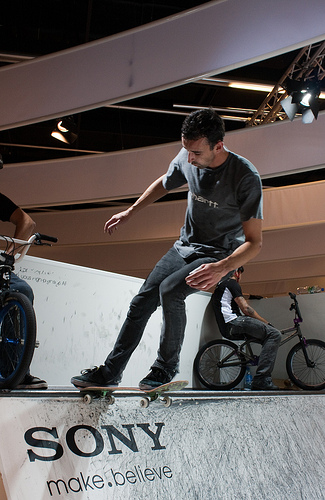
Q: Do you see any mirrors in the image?
A: No, there are no mirrors.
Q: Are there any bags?
A: No, there are no bags.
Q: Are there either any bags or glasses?
A: No, there are no bags or glasses.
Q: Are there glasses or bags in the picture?
A: No, there are no bags or glasses.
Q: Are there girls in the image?
A: No, there are no girls.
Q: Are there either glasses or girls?
A: No, there are no girls or glasses.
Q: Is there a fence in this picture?
A: No, there are no fences.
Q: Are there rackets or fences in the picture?
A: No, there are no fences or rackets.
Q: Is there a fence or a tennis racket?
A: No, there are no fences or rackets.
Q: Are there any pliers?
A: No, there are no pliers.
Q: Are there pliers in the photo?
A: No, there are no pliers.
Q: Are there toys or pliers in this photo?
A: No, there are no pliers or toys.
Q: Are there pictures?
A: No, there are no pictures.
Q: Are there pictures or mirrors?
A: No, there are no pictures or mirrors.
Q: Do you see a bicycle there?
A: Yes, there is a bicycle.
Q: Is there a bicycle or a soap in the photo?
A: Yes, there is a bicycle.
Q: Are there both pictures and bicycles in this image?
A: No, there is a bicycle but no pictures.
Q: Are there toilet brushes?
A: No, there are no toilet brushes.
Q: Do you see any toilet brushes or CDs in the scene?
A: No, there are no toilet brushes or cds.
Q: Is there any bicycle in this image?
A: Yes, there is a bicycle.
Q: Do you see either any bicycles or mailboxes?
A: Yes, there is a bicycle.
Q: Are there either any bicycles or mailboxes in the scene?
A: Yes, there is a bicycle.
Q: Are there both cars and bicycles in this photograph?
A: No, there is a bicycle but no cars.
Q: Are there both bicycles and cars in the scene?
A: No, there is a bicycle but no cars.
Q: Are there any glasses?
A: No, there are no glasses.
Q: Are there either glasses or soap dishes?
A: No, there are no glasses or soap dishes.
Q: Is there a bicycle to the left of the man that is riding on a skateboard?
A: Yes, there is a bicycle to the left of the man.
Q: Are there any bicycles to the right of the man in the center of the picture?
A: No, the bicycle is to the left of the man.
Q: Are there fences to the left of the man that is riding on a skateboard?
A: No, there is a bicycle to the left of the man.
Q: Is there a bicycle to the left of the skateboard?
A: Yes, there is a bicycle to the left of the skateboard.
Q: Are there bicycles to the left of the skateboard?
A: Yes, there is a bicycle to the left of the skateboard.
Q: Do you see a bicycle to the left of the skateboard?
A: Yes, there is a bicycle to the left of the skateboard.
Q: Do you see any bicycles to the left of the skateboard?
A: Yes, there is a bicycle to the left of the skateboard.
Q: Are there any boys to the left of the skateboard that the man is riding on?
A: No, there is a bicycle to the left of the skateboard.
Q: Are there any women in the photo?
A: No, there are no women.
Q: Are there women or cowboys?
A: No, there are no women or cowboys.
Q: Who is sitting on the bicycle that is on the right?
A: The man is sitting on the bicycle.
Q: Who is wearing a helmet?
A: The man is wearing a helmet.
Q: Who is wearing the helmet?
A: The man is wearing a helmet.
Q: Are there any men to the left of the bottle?
A: Yes, there is a man to the left of the bottle.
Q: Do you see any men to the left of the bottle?
A: Yes, there is a man to the left of the bottle.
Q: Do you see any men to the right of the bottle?
A: No, the man is to the left of the bottle.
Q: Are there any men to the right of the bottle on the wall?
A: No, the man is to the left of the bottle.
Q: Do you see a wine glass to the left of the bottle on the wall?
A: No, there is a man to the left of the bottle.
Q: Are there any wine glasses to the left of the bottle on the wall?
A: No, there is a man to the left of the bottle.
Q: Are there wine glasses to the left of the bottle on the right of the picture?
A: No, there is a man to the left of the bottle.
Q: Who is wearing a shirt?
A: The man is wearing a shirt.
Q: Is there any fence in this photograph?
A: No, there are no fences.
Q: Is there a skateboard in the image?
A: Yes, there is a skateboard.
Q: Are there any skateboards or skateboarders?
A: Yes, there is a skateboard.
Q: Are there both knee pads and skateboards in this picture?
A: No, there is a skateboard but no knee pads.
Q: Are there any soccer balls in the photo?
A: No, there are no soccer balls.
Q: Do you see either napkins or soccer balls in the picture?
A: No, there are no soccer balls or napkins.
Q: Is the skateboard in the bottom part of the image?
A: Yes, the skateboard is in the bottom of the image.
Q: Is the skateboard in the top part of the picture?
A: No, the skateboard is in the bottom of the image.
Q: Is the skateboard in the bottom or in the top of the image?
A: The skateboard is in the bottom of the image.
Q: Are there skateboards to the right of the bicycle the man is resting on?
A: Yes, there is a skateboard to the right of the bicycle.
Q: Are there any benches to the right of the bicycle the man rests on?
A: No, there is a skateboard to the right of the bicycle.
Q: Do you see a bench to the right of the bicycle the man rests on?
A: No, there is a skateboard to the right of the bicycle.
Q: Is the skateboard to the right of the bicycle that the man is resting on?
A: Yes, the skateboard is to the right of the bicycle.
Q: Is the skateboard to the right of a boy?
A: No, the skateboard is to the right of the bicycle.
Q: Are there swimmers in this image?
A: No, there are no swimmers.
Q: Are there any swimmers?
A: No, there are no swimmers.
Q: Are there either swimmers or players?
A: No, there are no swimmers or players.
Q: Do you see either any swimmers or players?
A: No, there are no swimmers or players.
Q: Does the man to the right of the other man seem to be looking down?
A: Yes, the man is looking down.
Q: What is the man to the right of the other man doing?
A: The man is looking down.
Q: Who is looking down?
A: The man is looking down.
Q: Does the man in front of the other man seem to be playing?
A: No, the man is looking down.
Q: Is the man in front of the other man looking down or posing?
A: The man is looking down.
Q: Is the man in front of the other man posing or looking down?
A: The man is looking down.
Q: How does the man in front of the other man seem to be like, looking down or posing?
A: The man is looking down.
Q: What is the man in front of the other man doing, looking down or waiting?
A: The man is looking down.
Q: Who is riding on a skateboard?
A: The man is riding on a skateboard.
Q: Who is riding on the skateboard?
A: The man is riding on a skateboard.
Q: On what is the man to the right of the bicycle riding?
A: The man is riding on a skateboard.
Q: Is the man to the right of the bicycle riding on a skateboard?
A: Yes, the man is riding on a skateboard.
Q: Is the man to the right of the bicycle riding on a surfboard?
A: No, the man is riding on a skateboard.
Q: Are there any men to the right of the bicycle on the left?
A: Yes, there is a man to the right of the bicycle.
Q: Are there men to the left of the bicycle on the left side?
A: No, the man is to the right of the bicycle.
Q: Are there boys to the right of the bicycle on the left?
A: No, there is a man to the right of the bicycle.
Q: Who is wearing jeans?
A: The man is wearing jeans.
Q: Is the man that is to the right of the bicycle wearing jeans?
A: Yes, the man is wearing jeans.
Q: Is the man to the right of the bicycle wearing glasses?
A: No, the man is wearing jeans.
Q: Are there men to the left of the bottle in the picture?
A: Yes, there is a man to the left of the bottle.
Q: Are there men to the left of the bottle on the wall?
A: Yes, there is a man to the left of the bottle.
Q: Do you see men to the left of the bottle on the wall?
A: Yes, there is a man to the left of the bottle.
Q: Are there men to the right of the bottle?
A: No, the man is to the left of the bottle.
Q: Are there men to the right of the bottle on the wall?
A: No, the man is to the left of the bottle.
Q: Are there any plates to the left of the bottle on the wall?
A: No, there is a man to the left of the bottle.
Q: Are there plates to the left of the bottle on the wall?
A: No, there is a man to the left of the bottle.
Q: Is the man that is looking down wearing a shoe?
A: Yes, the man is wearing a shoe.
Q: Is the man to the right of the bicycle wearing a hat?
A: No, the man is wearing a shoe.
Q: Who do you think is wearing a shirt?
A: The man is wearing a shirt.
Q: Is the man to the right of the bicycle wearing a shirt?
A: Yes, the man is wearing a shirt.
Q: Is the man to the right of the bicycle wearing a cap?
A: No, the man is wearing a shirt.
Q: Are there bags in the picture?
A: No, there are no bags.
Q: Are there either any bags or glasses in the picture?
A: No, there are no bags or glasses.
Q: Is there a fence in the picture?
A: No, there are no fences.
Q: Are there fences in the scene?
A: No, there are no fences.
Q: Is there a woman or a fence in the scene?
A: No, there are no fences or women.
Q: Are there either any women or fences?
A: No, there are no fences or women.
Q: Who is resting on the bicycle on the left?
A: The man is resting on the bicycle.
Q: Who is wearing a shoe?
A: The man is wearing a shoe.